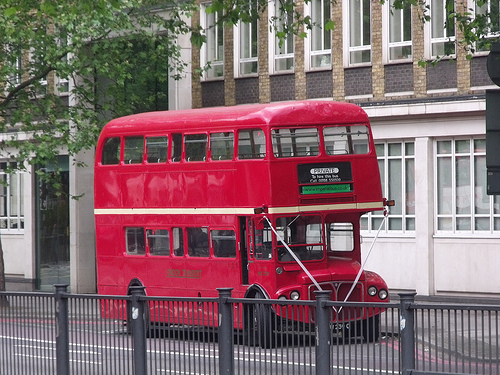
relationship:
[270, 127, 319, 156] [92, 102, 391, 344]
window on bus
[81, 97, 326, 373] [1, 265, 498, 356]
bus on pavement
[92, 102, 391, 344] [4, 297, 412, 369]
bus parked on street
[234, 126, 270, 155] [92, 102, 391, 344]
window belongs to bus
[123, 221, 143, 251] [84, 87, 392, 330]
window belongs to bus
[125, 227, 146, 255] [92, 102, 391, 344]
window belongs to bus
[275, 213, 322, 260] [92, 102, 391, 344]
window of a bus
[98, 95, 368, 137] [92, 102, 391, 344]
roof of a bus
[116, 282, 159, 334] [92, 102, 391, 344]
wheel of a bus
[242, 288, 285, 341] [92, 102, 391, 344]
wheel of a bus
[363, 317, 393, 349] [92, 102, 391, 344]
wheel of a bus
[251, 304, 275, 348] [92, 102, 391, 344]
wheel of a bus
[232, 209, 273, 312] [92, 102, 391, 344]
door of a bus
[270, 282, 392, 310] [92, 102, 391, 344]
lights of a bus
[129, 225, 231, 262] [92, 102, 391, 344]
windows on a bus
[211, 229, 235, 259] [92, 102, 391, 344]
windows on a bus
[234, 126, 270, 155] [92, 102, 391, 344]
window on a bus